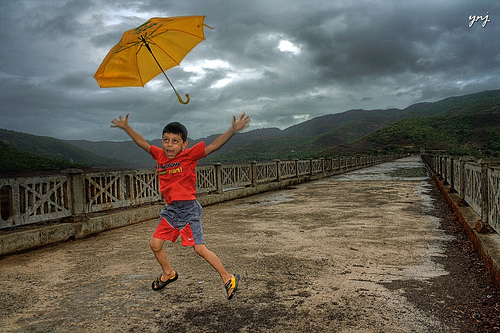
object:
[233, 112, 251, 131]
hands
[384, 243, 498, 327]
dirt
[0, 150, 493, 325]
ground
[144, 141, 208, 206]
red shirt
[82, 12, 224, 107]
umbrella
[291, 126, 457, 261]
path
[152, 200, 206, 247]
shorts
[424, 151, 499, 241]
fence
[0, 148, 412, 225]
fence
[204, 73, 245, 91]
sunlight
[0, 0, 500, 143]
clouds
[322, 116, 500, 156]
hill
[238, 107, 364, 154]
hill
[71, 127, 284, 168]
hill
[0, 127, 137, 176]
hill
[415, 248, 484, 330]
gravel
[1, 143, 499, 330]
bridge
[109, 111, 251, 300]
boy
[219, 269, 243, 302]
white frosting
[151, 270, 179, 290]
sandals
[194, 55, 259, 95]
light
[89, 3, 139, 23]
light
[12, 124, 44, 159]
grass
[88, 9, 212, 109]
umbrealla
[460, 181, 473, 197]
rail part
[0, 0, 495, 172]
sky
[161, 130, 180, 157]
face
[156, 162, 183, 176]
logo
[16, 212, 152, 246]
side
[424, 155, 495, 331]
side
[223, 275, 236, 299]
sandals